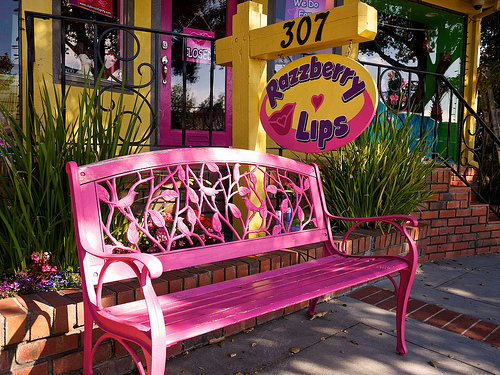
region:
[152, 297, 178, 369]
Zebra chasing other animals in the water.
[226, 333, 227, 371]
Zebra chasing other animals in the water.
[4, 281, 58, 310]
Zebra chasing other animals in the water.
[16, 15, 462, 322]
a pretty pink bench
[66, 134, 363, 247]
the back of the bench has a decorative design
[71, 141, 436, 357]
this pink bench is for sitting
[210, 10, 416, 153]
this is a sign for a business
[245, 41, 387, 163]
this sign has a picture of pink lips on it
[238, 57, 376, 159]
this sign is pink, yellow and purple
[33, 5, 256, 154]
the building behind the bench is colorful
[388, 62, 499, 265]
steps leading to the business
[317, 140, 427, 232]
a patch of grass in front of the business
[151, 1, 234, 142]
the door to the business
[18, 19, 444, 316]
this is store front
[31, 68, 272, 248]
this is an urban setting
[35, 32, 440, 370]
this is in a town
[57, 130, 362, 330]
this is a bench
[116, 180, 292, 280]
the bench has a floral pattern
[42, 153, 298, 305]
the bench is pink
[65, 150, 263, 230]
the bench back is metal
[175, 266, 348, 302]
the bench seat is wood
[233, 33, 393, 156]
this is a sign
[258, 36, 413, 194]
the sign says razzberry lips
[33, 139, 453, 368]
bench on the ground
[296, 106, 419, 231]
plants in a garden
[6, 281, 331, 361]
brick along the garden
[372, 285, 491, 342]
brick on the sidewalk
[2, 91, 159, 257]
plant in the garden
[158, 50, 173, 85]
handle on the door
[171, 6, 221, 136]
window on the door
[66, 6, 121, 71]
window on the building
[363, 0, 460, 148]
window on the building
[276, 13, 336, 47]
number on the post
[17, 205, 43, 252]
grass on a building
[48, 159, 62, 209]
grass on a building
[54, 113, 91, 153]
grass on a building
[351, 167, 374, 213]
grass on a building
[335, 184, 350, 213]
grass on a building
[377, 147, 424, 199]
grass on a building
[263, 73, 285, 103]
alphabet on a sign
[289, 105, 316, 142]
alphabet on a sign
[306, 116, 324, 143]
alphabet on a sign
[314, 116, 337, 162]
alphabet on a sign